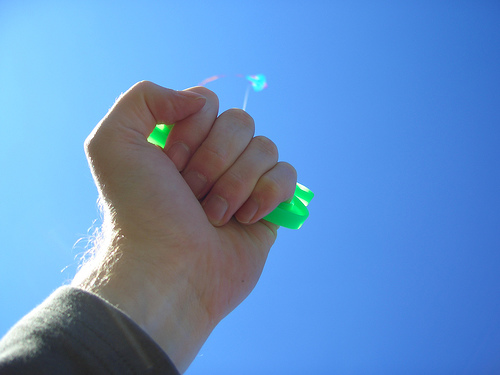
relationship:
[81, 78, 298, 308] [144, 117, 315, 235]
hand holding knife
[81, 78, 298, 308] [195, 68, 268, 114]
hand holding kite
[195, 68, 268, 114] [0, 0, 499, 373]
kite in sky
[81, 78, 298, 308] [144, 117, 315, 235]
hand grasping band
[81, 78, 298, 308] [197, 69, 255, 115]
hand holding kite string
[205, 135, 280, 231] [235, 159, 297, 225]
ring finger next to pinky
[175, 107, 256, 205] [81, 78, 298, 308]
middle finger on hand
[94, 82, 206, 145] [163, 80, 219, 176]
thumb touching index finger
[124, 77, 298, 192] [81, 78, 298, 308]
five fingers are on hand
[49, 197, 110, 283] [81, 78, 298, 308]
hairs are on hand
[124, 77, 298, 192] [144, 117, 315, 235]
fingers are wrapped around object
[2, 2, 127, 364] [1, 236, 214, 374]
light shining on arm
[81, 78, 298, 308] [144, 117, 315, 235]
hand holding object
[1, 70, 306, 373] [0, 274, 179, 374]
man has shirt sleeve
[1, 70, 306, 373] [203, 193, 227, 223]
man has fingernail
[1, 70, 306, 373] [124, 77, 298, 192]
man has knuckles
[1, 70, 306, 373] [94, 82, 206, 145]
man has thumb